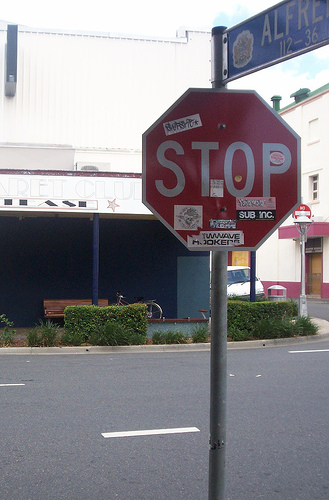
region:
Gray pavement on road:
[47, 372, 153, 450]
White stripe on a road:
[82, 406, 246, 473]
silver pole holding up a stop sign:
[188, 318, 238, 490]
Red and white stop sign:
[137, 107, 298, 251]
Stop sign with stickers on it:
[127, 81, 312, 275]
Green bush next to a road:
[47, 297, 203, 399]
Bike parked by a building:
[110, 289, 214, 356]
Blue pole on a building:
[86, 221, 124, 331]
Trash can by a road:
[263, 282, 293, 327]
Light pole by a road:
[287, 218, 326, 319]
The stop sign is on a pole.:
[123, 83, 311, 299]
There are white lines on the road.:
[76, 407, 219, 464]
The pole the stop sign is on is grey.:
[194, 261, 236, 496]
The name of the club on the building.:
[2, 174, 161, 226]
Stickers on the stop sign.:
[159, 112, 281, 248]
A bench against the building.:
[31, 294, 112, 324]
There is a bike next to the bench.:
[108, 283, 168, 320]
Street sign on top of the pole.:
[219, 0, 328, 55]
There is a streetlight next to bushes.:
[293, 211, 317, 324]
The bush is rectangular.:
[58, 299, 159, 342]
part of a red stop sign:
[153, 99, 278, 257]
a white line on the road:
[93, 420, 196, 441]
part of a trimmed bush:
[64, 297, 153, 331]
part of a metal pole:
[209, 251, 221, 491]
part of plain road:
[111, 372, 177, 419]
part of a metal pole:
[292, 235, 306, 293]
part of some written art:
[0, 172, 130, 214]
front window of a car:
[233, 271, 243, 284]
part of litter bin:
[266, 274, 289, 297]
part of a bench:
[41, 289, 65, 313]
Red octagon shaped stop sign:
[133, 85, 308, 257]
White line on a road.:
[97, 421, 200, 437]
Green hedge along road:
[64, 304, 149, 336]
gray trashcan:
[266, 283, 289, 306]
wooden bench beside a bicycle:
[40, 297, 108, 322]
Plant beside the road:
[23, 318, 59, 348]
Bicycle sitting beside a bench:
[112, 290, 164, 320]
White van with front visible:
[223, 262, 268, 298]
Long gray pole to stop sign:
[210, 251, 246, 499]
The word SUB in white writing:
[239, 210, 254, 219]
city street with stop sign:
[137, 92, 300, 456]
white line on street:
[77, 405, 194, 453]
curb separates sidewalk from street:
[4, 332, 204, 374]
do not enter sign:
[283, 198, 316, 250]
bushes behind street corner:
[230, 295, 326, 351]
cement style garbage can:
[266, 278, 293, 310]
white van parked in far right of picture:
[224, 260, 272, 310]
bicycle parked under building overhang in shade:
[103, 287, 170, 323]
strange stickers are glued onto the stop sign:
[159, 105, 281, 252]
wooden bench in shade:
[36, 292, 114, 339]